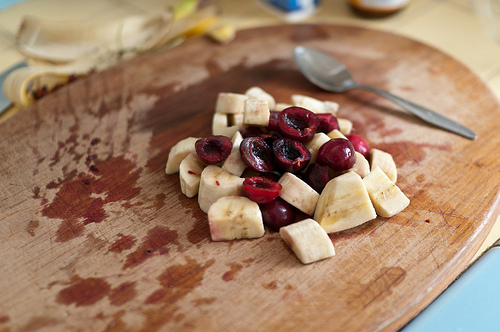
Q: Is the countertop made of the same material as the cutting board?
A: Yes, both the countertop and the cutting board are made of wood.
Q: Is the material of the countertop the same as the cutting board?
A: Yes, both the countertop and the cutting board are made of wood.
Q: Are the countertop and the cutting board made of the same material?
A: Yes, both the countertop and the cutting board are made of wood.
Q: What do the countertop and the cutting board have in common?
A: The material, both the countertop and the cutting board are wooden.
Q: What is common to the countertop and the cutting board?
A: The material, both the countertop and the cutting board are wooden.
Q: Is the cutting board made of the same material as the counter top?
A: Yes, both the cutting board and the counter top are made of wood.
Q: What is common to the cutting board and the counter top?
A: The material, both the cutting board and the counter top are wooden.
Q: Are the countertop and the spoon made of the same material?
A: No, the countertop is made of wood and the spoon is made of metal.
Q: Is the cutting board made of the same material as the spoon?
A: No, the cutting board is made of wood and the spoon is made of metal.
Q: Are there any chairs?
A: No, there are no chairs.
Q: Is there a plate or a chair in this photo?
A: No, there are no chairs or plates.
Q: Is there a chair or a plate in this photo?
A: No, there are no chairs or plates.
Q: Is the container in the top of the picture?
A: Yes, the container is in the top of the image.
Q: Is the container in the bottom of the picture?
A: No, the container is in the top of the image.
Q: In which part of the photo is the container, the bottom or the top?
A: The container is in the top of the image.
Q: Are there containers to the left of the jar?
A: Yes, there is a container to the left of the jar.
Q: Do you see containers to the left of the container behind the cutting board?
A: Yes, there is a container to the left of the jar.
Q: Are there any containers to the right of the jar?
A: No, the container is to the left of the jar.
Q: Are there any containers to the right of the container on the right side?
A: No, the container is to the left of the jar.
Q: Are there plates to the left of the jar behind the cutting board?
A: No, there is a container to the left of the jar.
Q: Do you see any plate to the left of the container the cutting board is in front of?
A: No, there is a container to the left of the jar.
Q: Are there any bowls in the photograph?
A: No, there are no bowls.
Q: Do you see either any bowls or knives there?
A: No, there are no bowls or knives.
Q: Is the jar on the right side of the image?
A: Yes, the jar is on the right of the image.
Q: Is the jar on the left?
A: No, the jar is on the right of the image.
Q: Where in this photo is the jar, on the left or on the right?
A: The jar is on the right of the image.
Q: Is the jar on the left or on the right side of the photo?
A: The jar is on the right of the image.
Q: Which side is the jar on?
A: The jar is on the right of the image.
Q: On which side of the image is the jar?
A: The jar is on the right of the image.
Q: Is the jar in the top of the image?
A: Yes, the jar is in the top of the image.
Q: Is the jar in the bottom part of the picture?
A: No, the jar is in the top of the image.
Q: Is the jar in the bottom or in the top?
A: The jar is in the top of the image.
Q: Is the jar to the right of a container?
A: Yes, the jar is to the right of a container.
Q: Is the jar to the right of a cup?
A: No, the jar is to the right of a container.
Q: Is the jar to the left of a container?
A: No, the jar is to the right of a container.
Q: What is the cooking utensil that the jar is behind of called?
A: The cooking utensil is a cutting board.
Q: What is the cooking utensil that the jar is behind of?
A: The cooking utensil is a cutting board.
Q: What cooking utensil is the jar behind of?
A: The jar is behind the cutting board.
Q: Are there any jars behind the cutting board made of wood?
A: Yes, there is a jar behind the cutting board.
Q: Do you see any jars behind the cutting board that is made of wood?
A: Yes, there is a jar behind the cutting board.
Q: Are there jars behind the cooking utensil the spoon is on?
A: Yes, there is a jar behind the cutting board.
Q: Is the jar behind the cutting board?
A: Yes, the jar is behind the cutting board.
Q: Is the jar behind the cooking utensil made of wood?
A: Yes, the jar is behind the cutting board.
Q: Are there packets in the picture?
A: No, there are no packets.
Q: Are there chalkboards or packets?
A: No, there are no packets or chalkboards.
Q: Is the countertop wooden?
A: Yes, the countertop is wooden.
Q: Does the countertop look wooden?
A: Yes, the countertop is wooden.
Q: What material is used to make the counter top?
A: The counter top is made of wood.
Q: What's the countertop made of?
A: The counter top is made of wood.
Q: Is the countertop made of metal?
A: No, the countertop is made of wood.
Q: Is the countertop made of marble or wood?
A: The countertop is made of wood.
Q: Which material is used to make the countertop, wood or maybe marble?
A: The countertop is made of wood.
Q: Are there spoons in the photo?
A: Yes, there is a spoon.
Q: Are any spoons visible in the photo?
A: Yes, there is a spoon.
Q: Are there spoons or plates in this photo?
A: Yes, there is a spoon.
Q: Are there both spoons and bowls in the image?
A: No, there is a spoon but no bowls.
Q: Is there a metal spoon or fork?
A: Yes, there is a metal spoon.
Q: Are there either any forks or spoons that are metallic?
A: Yes, the spoon is metallic.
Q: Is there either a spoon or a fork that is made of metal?
A: Yes, the spoon is made of metal.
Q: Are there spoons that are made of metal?
A: Yes, there is a spoon that is made of metal.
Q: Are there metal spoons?
A: Yes, there is a spoon that is made of metal.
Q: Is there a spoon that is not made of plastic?
A: Yes, there is a spoon that is made of metal.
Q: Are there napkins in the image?
A: No, there are no napkins.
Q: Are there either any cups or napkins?
A: No, there are no napkins or cups.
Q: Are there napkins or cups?
A: No, there are no napkins or cups.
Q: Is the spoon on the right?
A: Yes, the spoon is on the right of the image.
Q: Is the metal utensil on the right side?
A: Yes, the spoon is on the right of the image.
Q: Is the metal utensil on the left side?
A: No, the spoon is on the right of the image.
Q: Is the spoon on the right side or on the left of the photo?
A: The spoon is on the right of the image.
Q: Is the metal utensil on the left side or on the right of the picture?
A: The spoon is on the right of the image.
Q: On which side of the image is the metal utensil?
A: The spoon is on the right of the image.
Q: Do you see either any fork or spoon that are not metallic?
A: No, there is a spoon but it is metallic.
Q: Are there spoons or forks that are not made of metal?
A: No, there is a spoon but it is made of metal.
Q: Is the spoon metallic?
A: Yes, the spoon is metallic.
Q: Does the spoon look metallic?
A: Yes, the spoon is metallic.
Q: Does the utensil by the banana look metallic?
A: Yes, the spoon is metallic.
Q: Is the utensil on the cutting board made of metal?
A: Yes, the spoon is made of metal.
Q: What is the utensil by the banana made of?
A: The spoon is made of metal.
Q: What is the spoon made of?
A: The spoon is made of metal.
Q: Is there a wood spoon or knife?
A: No, there is a spoon but it is metallic.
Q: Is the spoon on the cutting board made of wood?
A: No, the spoon is made of metal.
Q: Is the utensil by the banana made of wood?
A: No, the spoon is made of metal.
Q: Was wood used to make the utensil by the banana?
A: No, the spoon is made of metal.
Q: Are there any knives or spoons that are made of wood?
A: No, there is a spoon but it is made of metal.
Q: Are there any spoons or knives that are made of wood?
A: No, there is a spoon but it is made of metal.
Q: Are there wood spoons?
A: No, there is a spoon but it is made of metal.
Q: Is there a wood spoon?
A: No, there is a spoon but it is made of metal.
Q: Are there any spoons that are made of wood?
A: No, there is a spoon but it is made of metal.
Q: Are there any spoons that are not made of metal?
A: No, there is a spoon but it is made of metal.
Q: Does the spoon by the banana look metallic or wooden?
A: The spoon is metallic.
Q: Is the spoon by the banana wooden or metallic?
A: The spoon is metallic.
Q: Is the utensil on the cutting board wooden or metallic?
A: The spoon is metallic.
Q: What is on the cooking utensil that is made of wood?
A: The spoon is on the cutting board.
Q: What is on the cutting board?
A: The spoon is on the cutting board.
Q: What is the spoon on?
A: The spoon is on the cutting board.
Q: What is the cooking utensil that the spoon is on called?
A: The cooking utensil is a cutting board.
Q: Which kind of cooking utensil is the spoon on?
A: The spoon is on the cutting board.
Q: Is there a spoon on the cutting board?
A: Yes, there is a spoon on the cutting board.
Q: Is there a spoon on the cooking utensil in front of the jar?
A: Yes, there is a spoon on the cutting board.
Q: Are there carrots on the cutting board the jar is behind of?
A: No, there is a spoon on the cutting board.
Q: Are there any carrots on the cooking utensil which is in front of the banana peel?
A: No, there is a spoon on the cutting board.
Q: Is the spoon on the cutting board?
A: Yes, the spoon is on the cutting board.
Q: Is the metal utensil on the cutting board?
A: Yes, the spoon is on the cutting board.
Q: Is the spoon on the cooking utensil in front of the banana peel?
A: Yes, the spoon is on the cutting board.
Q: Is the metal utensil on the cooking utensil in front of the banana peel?
A: Yes, the spoon is on the cutting board.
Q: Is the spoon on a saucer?
A: No, the spoon is on the cutting board.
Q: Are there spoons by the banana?
A: Yes, there is a spoon by the banana.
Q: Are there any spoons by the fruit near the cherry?
A: Yes, there is a spoon by the banana.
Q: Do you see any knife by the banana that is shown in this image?
A: No, there is a spoon by the banana.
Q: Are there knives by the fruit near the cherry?
A: No, there is a spoon by the banana.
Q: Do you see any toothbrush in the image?
A: No, there are no toothbrushes.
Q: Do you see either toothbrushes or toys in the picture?
A: No, there are no toothbrushes or toys.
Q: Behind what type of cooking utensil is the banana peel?
A: The banana peel is behind the cutting board.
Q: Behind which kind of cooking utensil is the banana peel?
A: The banana peel is behind the cutting board.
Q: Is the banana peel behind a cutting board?
A: Yes, the banana peel is behind a cutting board.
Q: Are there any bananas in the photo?
A: Yes, there is a banana.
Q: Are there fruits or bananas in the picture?
A: Yes, there is a banana.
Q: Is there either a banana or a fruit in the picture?
A: Yes, there is a banana.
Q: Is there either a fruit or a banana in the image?
A: Yes, there is a banana.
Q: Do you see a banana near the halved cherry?
A: Yes, there is a banana near the cherry.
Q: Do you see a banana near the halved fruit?
A: Yes, there is a banana near the cherry.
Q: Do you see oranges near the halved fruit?
A: No, there is a banana near the cherry.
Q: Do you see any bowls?
A: No, there are no bowls.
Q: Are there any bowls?
A: No, there are no bowls.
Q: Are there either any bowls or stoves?
A: No, there are no bowls or stoves.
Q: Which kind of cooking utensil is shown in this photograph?
A: The cooking utensil is a cutting board.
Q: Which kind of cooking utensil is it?
A: The cooking utensil is a cutting board.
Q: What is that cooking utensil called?
A: This is a cutting board.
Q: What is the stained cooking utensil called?
A: The cooking utensil is a cutting board.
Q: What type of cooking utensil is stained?
A: The cooking utensil is a cutting board.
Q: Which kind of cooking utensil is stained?
A: The cooking utensil is a cutting board.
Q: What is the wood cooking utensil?
A: The cooking utensil is a cutting board.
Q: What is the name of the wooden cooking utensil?
A: The cooking utensil is a cutting board.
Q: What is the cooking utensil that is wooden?
A: The cooking utensil is a cutting board.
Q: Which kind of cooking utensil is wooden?
A: The cooking utensil is a cutting board.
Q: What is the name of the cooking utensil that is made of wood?
A: The cooking utensil is a cutting board.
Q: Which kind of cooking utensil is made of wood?
A: The cooking utensil is a cutting board.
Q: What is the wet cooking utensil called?
A: The cooking utensil is a cutting board.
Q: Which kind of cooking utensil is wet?
A: The cooking utensil is a cutting board.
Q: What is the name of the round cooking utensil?
A: The cooking utensil is a cutting board.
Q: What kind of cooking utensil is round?
A: The cooking utensil is a cutting board.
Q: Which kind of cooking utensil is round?
A: The cooking utensil is a cutting board.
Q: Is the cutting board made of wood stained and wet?
A: Yes, the cutting board is stained and wet.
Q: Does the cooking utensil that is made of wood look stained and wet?
A: Yes, the cutting board is stained and wet.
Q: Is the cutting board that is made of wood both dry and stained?
A: No, the cutting board is stained but wet.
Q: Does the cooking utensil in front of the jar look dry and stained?
A: No, the cutting board is stained but wet.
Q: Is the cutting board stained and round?
A: Yes, the cutting board is stained and round.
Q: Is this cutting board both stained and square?
A: No, the cutting board is stained but round.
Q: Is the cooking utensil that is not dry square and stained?
A: No, the cutting board is stained but round.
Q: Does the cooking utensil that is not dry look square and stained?
A: No, the cutting board is stained but round.